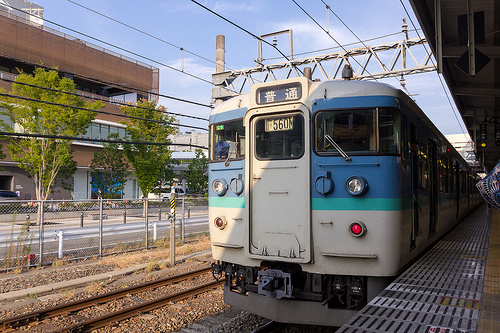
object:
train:
[209, 76, 483, 327]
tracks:
[2, 260, 227, 332]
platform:
[332, 196, 500, 332]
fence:
[0, 199, 212, 271]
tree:
[0, 59, 106, 226]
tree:
[118, 97, 180, 218]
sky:
[43, 0, 472, 134]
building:
[0, 15, 159, 205]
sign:
[259, 88, 301, 102]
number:
[265, 118, 298, 130]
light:
[350, 221, 364, 235]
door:
[251, 113, 309, 261]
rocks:
[167, 313, 176, 323]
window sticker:
[212, 125, 228, 130]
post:
[170, 183, 175, 265]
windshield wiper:
[320, 118, 351, 162]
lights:
[212, 176, 228, 194]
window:
[92, 172, 125, 199]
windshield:
[316, 108, 397, 152]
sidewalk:
[0, 207, 210, 268]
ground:
[2, 209, 332, 332]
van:
[140, 184, 187, 201]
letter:
[287, 117, 295, 128]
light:
[347, 178, 364, 195]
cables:
[0, 131, 205, 150]